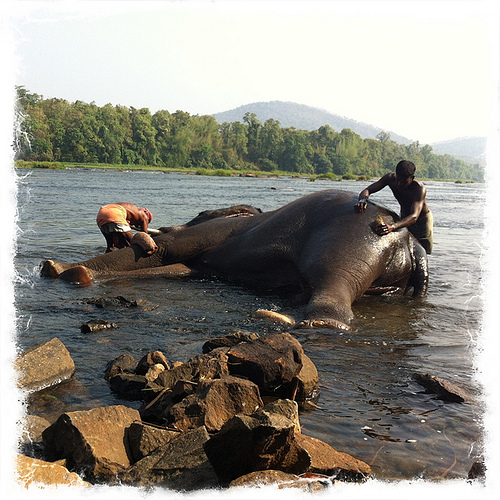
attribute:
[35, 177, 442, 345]
elephant — bathed, washed, wet, gray, large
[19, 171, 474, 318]
body — water, large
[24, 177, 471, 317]
water — murkey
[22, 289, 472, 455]
rocks — big, large, brown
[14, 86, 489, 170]
landscape — grassy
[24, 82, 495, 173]
area — large, forested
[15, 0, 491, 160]
sky — clear, blue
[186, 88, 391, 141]
hill — large, forested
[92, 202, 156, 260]
man — bent, washing, shirtless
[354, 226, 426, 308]
back side — huge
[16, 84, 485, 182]
trees — green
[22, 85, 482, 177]
leaves — green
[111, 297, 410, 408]
spots — foam, white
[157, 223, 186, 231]
trunk — brown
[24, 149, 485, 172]
grass — growing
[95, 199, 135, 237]
clothing — red, yellow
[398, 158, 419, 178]
hair — black